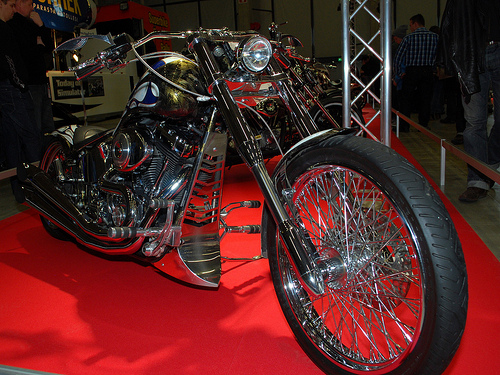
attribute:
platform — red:
[3, 98, 494, 366]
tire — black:
[255, 149, 459, 372]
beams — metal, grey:
[333, 0, 394, 137]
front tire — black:
[266, 133, 468, 373]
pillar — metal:
[339, 0, 391, 146]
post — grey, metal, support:
[340, 0, 395, 140]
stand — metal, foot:
[107, 224, 169, 241]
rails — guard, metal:
[343, 87, 497, 194]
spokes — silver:
[278, 164, 423, 372]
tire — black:
[261, 135, 466, 374]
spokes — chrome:
[282, 200, 392, 332]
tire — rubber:
[240, 107, 480, 373]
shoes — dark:
[454, 177, 491, 207]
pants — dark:
[404, 67, 439, 147]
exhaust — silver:
[12, 162, 159, 259]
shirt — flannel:
[398, 31, 456, 89]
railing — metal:
[409, 117, 498, 179]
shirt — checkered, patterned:
[378, 11, 462, 81]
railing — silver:
[393, 113, 494, 185]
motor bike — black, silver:
[26, 23, 478, 374]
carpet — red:
[0, 130, 497, 372]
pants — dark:
[455, 73, 498, 189]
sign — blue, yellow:
[32, 0, 92, 31]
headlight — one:
[235, 30, 275, 75]